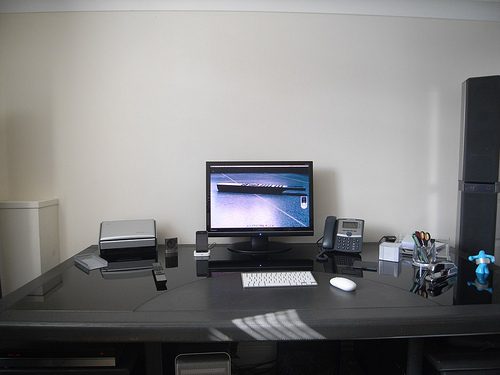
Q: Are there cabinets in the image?
A: Yes, there is a cabinet.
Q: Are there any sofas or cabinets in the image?
A: Yes, there is a cabinet.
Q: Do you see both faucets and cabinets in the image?
A: No, there is a cabinet but no faucets.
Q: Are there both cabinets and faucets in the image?
A: No, there is a cabinet but no faucets.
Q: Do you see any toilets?
A: No, there are no toilets.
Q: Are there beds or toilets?
A: No, there are no toilets or beds.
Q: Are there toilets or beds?
A: No, there are no toilets or beds.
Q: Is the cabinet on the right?
A: No, the cabinet is on the left of the image.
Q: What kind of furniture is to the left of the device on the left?
A: The piece of furniture is a cabinet.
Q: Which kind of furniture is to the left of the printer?
A: The piece of furniture is a cabinet.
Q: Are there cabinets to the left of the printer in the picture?
A: Yes, there is a cabinet to the left of the printer.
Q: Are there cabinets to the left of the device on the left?
A: Yes, there is a cabinet to the left of the printer.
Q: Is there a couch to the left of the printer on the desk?
A: No, there is a cabinet to the left of the printer.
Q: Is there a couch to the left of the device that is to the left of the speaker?
A: No, there is a cabinet to the left of the printer.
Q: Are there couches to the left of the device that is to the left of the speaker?
A: No, there is a cabinet to the left of the printer.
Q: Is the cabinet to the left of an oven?
A: No, the cabinet is to the left of the printer.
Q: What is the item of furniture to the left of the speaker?
A: The piece of furniture is a cabinet.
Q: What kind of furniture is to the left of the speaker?
A: The piece of furniture is a cabinet.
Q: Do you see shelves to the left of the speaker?
A: No, there is a cabinet to the left of the speaker.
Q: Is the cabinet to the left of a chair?
A: No, the cabinet is to the left of a speaker.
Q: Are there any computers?
A: Yes, there is a computer.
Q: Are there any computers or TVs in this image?
A: Yes, there is a computer.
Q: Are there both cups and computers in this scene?
A: Yes, there are both a computer and a cup.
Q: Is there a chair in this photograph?
A: No, there are no chairs.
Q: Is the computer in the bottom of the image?
A: Yes, the computer is in the bottom of the image.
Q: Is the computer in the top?
A: No, the computer is in the bottom of the image.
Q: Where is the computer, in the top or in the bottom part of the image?
A: The computer is in the bottom of the image.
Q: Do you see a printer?
A: Yes, there is a printer.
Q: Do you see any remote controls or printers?
A: Yes, there is a printer.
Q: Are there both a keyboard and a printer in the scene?
A: Yes, there are both a printer and a keyboard.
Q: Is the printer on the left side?
A: Yes, the printer is on the left of the image.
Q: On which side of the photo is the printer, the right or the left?
A: The printer is on the left of the image.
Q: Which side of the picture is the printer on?
A: The printer is on the left of the image.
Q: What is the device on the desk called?
A: The device is a printer.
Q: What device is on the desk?
A: The device is a printer.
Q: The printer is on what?
A: The printer is on the desk.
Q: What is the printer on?
A: The printer is on the desk.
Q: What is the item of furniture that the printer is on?
A: The piece of furniture is a desk.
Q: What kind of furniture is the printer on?
A: The printer is on the desk.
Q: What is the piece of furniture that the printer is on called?
A: The piece of furniture is a desk.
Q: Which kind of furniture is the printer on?
A: The printer is on the desk.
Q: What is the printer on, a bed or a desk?
A: The printer is on a desk.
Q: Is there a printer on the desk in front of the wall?
A: Yes, there is a printer on the desk.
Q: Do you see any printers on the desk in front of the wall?
A: Yes, there is a printer on the desk.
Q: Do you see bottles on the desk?
A: No, there is a printer on the desk.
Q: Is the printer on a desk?
A: Yes, the printer is on a desk.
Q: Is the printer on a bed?
A: No, the printer is on a desk.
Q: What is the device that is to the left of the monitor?
A: The device is a printer.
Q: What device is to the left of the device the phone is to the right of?
A: The device is a printer.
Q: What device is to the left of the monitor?
A: The device is a printer.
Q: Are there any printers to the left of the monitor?
A: Yes, there is a printer to the left of the monitor.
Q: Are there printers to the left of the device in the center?
A: Yes, there is a printer to the left of the monitor.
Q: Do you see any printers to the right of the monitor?
A: No, the printer is to the left of the monitor.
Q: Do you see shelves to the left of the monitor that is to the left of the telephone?
A: No, there is a printer to the left of the monitor.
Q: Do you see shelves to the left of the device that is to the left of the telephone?
A: No, there is a printer to the left of the monitor.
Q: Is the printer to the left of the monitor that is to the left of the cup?
A: Yes, the printer is to the left of the monitor.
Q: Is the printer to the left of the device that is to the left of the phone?
A: Yes, the printer is to the left of the monitor.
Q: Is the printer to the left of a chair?
A: No, the printer is to the left of the monitor.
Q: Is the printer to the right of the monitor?
A: No, the printer is to the left of the monitor.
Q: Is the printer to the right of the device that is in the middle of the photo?
A: No, the printer is to the left of the monitor.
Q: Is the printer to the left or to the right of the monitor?
A: The printer is to the left of the monitor.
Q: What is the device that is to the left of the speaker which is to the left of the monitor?
A: The device is a printer.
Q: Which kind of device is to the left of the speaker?
A: The device is a printer.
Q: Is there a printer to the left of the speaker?
A: Yes, there is a printer to the left of the speaker.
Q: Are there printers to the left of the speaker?
A: Yes, there is a printer to the left of the speaker.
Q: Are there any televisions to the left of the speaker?
A: No, there is a printer to the left of the speaker.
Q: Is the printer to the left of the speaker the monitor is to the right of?
A: Yes, the printer is to the left of the speaker.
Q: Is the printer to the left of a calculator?
A: No, the printer is to the left of the speaker.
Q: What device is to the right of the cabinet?
A: The device is a printer.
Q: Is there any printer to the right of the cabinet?
A: Yes, there is a printer to the right of the cabinet.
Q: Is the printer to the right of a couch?
A: No, the printer is to the right of the cabinet.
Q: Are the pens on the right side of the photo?
A: Yes, the pens are on the right of the image.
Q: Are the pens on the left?
A: No, the pens are on the right of the image.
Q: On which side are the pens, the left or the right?
A: The pens are on the right of the image.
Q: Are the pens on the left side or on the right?
A: The pens are on the right of the image.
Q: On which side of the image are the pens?
A: The pens are on the right of the image.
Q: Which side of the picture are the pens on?
A: The pens are on the right of the image.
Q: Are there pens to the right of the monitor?
A: Yes, there are pens to the right of the monitor.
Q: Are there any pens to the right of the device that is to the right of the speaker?
A: Yes, there are pens to the right of the monitor.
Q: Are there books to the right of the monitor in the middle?
A: No, there are pens to the right of the monitor.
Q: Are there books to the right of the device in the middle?
A: No, there are pens to the right of the monitor.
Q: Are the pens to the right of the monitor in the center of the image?
A: Yes, the pens are to the right of the monitor.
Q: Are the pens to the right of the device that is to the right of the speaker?
A: Yes, the pens are to the right of the monitor.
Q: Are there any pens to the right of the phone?
A: Yes, there are pens to the right of the phone.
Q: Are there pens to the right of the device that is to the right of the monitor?
A: Yes, there are pens to the right of the phone.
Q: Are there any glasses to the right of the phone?
A: No, there are pens to the right of the phone.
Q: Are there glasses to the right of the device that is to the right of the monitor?
A: No, there are pens to the right of the phone.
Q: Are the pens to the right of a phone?
A: Yes, the pens are to the right of a phone.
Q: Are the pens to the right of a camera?
A: No, the pens are to the right of a phone.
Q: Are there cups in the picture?
A: Yes, there is a cup.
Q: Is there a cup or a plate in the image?
A: Yes, there is a cup.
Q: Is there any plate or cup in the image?
A: Yes, there is a cup.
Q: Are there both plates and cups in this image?
A: No, there is a cup but no plates.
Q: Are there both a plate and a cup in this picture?
A: No, there is a cup but no plates.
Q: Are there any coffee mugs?
A: No, there are no coffee mugs.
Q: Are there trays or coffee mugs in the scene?
A: No, there are no coffee mugs or trays.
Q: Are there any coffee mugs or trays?
A: No, there are no coffee mugs or trays.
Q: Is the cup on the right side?
A: Yes, the cup is on the right of the image.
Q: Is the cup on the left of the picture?
A: No, the cup is on the right of the image.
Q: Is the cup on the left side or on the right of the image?
A: The cup is on the right of the image.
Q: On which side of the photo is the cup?
A: The cup is on the right of the image.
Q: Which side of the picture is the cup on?
A: The cup is on the right of the image.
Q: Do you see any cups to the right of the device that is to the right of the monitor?
A: Yes, there is a cup to the right of the phone.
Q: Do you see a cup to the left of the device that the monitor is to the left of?
A: No, the cup is to the right of the telephone.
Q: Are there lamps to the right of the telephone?
A: No, there is a cup to the right of the telephone.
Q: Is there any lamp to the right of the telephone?
A: No, there is a cup to the right of the telephone.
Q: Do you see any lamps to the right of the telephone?
A: No, there is a cup to the right of the telephone.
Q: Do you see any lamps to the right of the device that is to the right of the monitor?
A: No, there is a cup to the right of the telephone.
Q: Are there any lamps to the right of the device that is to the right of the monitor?
A: No, there is a cup to the right of the telephone.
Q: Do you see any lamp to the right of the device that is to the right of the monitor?
A: No, there is a cup to the right of the telephone.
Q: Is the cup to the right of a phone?
A: Yes, the cup is to the right of a phone.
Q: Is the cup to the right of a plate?
A: No, the cup is to the right of a phone.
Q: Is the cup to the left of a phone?
A: No, the cup is to the right of a phone.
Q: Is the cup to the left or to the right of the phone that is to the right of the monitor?
A: The cup is to the right of the telephone.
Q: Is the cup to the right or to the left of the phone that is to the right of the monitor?
A: The cup is to the right of the telephone.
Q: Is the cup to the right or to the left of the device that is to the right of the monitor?
A: The cup is to the right of the telephone.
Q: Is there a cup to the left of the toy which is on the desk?
A: Yes, there is a cup to the left of the toy.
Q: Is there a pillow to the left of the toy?
A: No, there is a cup to the left of the toy.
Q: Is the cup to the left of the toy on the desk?
A: Yes, the cup is to the left of the toy.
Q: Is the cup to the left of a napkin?
A: No, the cup is to the left of the toy.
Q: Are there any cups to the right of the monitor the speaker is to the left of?
A: Yes, there is a cup to the right of the monitor.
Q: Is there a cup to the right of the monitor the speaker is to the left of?
A: Yes, there is a cup to the right of the monitor.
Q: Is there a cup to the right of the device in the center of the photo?
A: Yes, there is a cup to the right of the monitor.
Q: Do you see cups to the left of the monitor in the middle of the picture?
A: No, the cup is to the right of the monitor.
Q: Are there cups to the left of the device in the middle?
A: No, the cup is to the right of the monitor.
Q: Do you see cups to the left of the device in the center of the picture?
A: No, the cup is to the right of the monitor.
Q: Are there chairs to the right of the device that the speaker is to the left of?
A: No, there is a cup to the right of the monitor.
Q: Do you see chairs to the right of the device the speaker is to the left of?
A: No, there is a cup to the right of the monitor.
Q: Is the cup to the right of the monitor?
A: Yes, the cup is to the right of the monitor.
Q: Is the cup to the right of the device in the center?
A: Yes, the cup is to the right of the monitor.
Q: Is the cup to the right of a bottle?
A: No, the cup is to the right of the monitor.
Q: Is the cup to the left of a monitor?
A: No, the cup is to the right of a monitor.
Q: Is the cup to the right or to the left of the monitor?
A: The cup is to the right of the monitor.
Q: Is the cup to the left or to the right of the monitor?
A: The cup is to the right of the monitor.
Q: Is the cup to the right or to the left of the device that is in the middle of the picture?
A: The cup is to the right of the monitor.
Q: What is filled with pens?
A: The cup is filled with pens.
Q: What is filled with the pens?
A: The cup is filled with pens.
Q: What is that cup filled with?
A: The cup is filled with pens.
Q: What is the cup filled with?
A: The cup is filled with pens.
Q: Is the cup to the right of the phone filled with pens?
A: Yes, the cup is filled with pens.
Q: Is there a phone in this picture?
A: Yes, there is a phone.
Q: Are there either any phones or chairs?
A: Yes, there is a phone.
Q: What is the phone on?
A: The phone is on the desk.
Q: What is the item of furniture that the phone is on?
A: The piece of furniture is a desk.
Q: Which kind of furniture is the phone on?
A: The phone is on the desk.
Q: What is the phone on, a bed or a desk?
A: The phone is on a desk.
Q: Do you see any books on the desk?
A: No, there is a phone on the desk.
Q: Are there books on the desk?
A: No, there is a phone on the desk.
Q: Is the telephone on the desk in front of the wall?
A: Yes, the telephone is on the desk.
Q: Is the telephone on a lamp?
A: No, the telephone is on the desk.